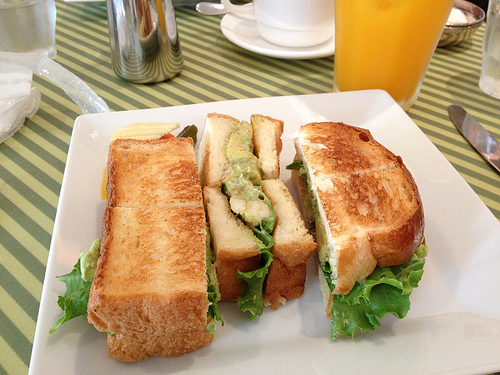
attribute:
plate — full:
[58, 88, 479, 364]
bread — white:
[207, 199, 250, 306]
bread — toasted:
[316, 130, 381, 217]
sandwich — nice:
[58, 137, 476, 340]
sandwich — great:
[138, 133, 439, 300]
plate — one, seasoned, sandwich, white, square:
[27, 80, 490, 373]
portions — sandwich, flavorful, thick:
[93, 115, 424, 365]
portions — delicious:
[80, 98, 440, 358]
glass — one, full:
[317, 3, 457, 103]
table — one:
[6, 13, 493, 345]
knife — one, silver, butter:
[445, 88, 498, 168]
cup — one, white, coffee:
[216, 5, 341, 65]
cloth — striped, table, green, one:
[172, 65, 272, 97]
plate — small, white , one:
[210, 6, 333, 66]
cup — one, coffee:
[230, 5, 335, 49]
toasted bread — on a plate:
[115, 142, 194, 286]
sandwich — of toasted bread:
[116, 301, 195, 351]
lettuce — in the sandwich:
[357, 282, 409, 317]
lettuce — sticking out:
[362, 276, 405, 320]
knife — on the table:
[445, 99, 485, 151]